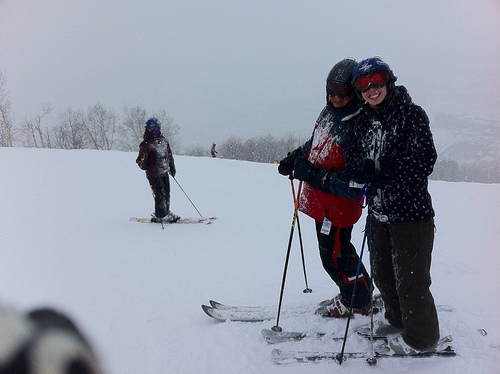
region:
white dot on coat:
[418, 211, 426, 220]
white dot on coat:
[407, 213, 417, 221]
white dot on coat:
[397, 211, 404, 223]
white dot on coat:
[406, 205, 414, 210]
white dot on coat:
[417, 134, 424, 143]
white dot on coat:
[426, 155, 436, 163]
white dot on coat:
[421, 163, 428, 172]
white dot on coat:
[393, 181, 402, 190]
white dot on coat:
[342, 160, 348, 167]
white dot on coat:
[358, 119, 365, 128]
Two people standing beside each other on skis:
[202, 38, 493, 368]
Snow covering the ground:
[1, 142, 497, 371]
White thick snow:
[1, 147, 498, 372]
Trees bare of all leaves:
[1, 85, 488, 180]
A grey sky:
[3, 4, 498, 181]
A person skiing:
[113, 116, 224, 234]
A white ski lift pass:
[313, 210, 338, 239]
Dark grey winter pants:
[361, 212, 448, 349]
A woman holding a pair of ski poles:
[204, 54, 379, 342]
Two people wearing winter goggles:
[259, 49, 460, 344]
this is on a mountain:
[19, 41, 428, 314]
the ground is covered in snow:
[62, 219, 197, 316]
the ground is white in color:
[48, 211, 206, 322]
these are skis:
[147, 201, 431, 371]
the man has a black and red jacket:
[310, 102, 382, 239]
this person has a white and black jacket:
[355, 112, 497, 210]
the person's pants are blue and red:
[317, 216, 392, 313]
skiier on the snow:
[123, 103, 233, 240]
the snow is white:
[30, 181, 97, 246]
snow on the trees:
[34, 112, 96, 146]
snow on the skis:
[285, 348, 323, 363]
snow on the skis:
[187, 209, 207, 228]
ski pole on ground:
[242, 186, 290, 331]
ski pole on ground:
[318, 313, 351, 365]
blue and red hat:
[354, 62, 386, 97]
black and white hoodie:
[343, 83, 457, 228]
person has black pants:
[374, 220, 452, 341]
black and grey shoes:
[361, 314, 423, 356]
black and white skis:
[270, 343, 436, 373]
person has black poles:
[283, 171, 445, 365]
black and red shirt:
[299, 107, 358, 228]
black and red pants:
[311, 201, 366, 317]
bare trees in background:
[25, 87, 239, 152]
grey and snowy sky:
[55, 7, 247, 101]